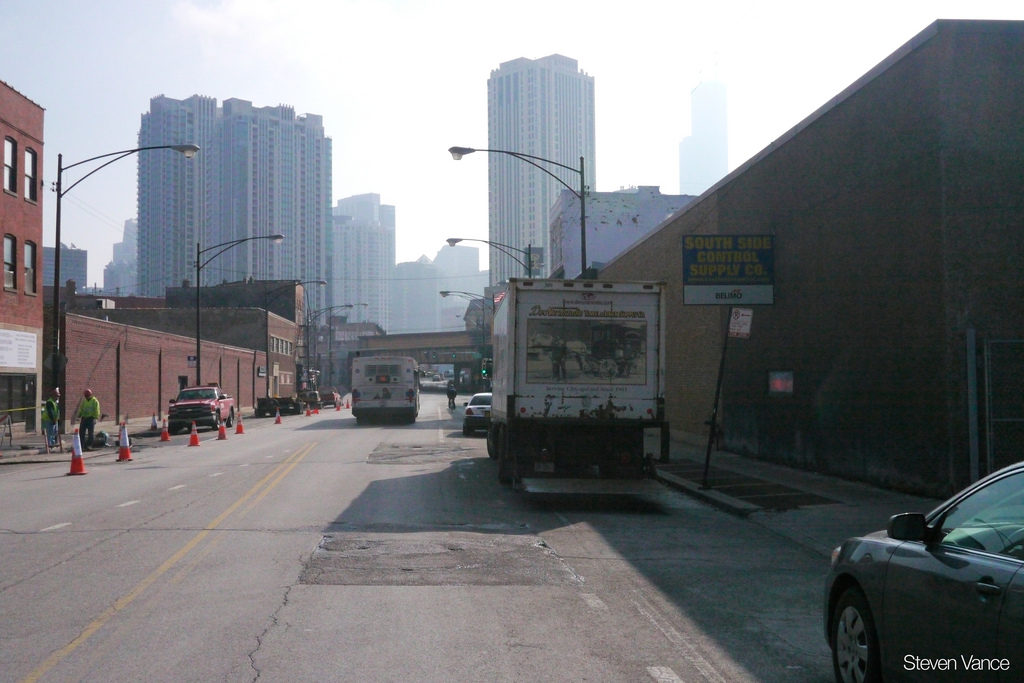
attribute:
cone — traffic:
[50, 425, 96, 488]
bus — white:
[337, 348, 430, 418]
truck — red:
[80, 218, 310, 409]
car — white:
[443, 386, 480, 423]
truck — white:
[432, 287, 675, 646]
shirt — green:
[80, 406, 93, 426]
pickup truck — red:
[153, 365, 247, 484]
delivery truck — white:
[436, 289, 665, 560]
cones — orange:
[91, 365, 159, 497]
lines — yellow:
[56, 414, 311, 667]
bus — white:
[354, 362, 396, 460]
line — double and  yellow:
[71, 539, 173, 619]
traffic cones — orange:
[65, 302, 364, 454]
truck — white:
[545, 315, 602, 376]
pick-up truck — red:
[173, 397, 215, 426]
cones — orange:
[102, 405, 178, 460]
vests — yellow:
[71, 410, 100, 411]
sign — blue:
[673, 226, 780, 313]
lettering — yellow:
[690, 239, 764, 281]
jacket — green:
[83, 403, 99, 423]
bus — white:
[347, 343, 423, 426]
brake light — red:
[405, 384, 419, 410]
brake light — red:
[349, 382, 360, 404]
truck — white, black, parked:
[487, 271, 675, 492]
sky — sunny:
[8, 1, 1022, 283]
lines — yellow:
[16, 444, 315, 680]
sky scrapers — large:
[121, 83, 398, 365]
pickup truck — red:
[177, 374, 238, 474]